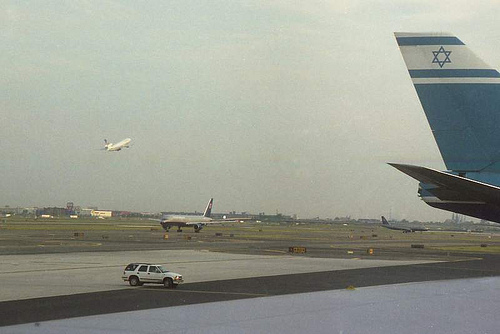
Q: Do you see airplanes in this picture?
A: Yes, there is an airplane.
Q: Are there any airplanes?
A: Yes, there is an airplane.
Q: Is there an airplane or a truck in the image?
A: Yes, there is an airplane.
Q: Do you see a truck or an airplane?
A: Yes, there is an airplane.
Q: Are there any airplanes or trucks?
A: Yes, there is an airplane.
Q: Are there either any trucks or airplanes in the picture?
A: Yes, there is an airplane.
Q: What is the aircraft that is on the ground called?
A: The aircraft is an airplane.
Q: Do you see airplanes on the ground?
A: Yes, there is an airplane on the ground.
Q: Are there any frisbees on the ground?
A: No, there is an airplane on the ground.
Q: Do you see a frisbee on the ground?
A: No, there is an airplane on the ground.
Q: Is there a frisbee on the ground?
A: No, there is an airplane on the ground.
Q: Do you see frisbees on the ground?
A: No, there is an airplane on the ground.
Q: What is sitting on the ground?
A: The airplane is sitting on the ground.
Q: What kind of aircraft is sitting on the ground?
A: The aircraft is an airplane.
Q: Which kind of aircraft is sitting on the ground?
A: The aircraft is an airplane.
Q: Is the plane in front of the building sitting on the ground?
A: Yes, the airplane is sitting on the ground.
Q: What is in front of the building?
A: The airplane is in front of the building.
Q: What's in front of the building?
A: The airplane is in front of the building.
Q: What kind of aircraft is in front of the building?
A: The aircraft is an airplane.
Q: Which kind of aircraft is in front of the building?
A: The aircraft is an airplane.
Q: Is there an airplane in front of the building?
A: Yes, there is an airplane in front of the building.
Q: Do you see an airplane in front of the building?
A: Yes, there is an airplane in front of the building.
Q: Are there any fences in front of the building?
A: No, there is an airplane in front of the building.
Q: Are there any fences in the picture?
A: No, there are no fences.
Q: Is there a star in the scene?
A: Yes, there is a star.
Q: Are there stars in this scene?
A: Yes, there is a star.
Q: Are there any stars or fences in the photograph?
A: Yes, there is a star.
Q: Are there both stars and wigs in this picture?
A: No, there is a star but no wigs.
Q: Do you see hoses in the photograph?
A: No, there are no hoses.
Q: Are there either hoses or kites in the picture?
A: No, there are no hoses or kites.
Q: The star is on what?
A: The star is on the plane.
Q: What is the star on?
A: The star is on the plane.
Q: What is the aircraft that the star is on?
A: The aircraft is an airplane.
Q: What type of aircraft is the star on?
A: The star is on the airplane.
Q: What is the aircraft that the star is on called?
A: The aircraft is an airplane.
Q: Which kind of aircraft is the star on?
A: The star is on the airplane.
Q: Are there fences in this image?
A: No, there are no fences.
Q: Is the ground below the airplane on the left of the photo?
A: Yes, the ground is below the plane.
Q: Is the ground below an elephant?
A: No, the ground is below the plane.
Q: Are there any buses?
A: No, there are no buses.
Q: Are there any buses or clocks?
A: No, there are no buses or clocks.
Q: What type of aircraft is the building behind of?
A: The building is behind the airplane.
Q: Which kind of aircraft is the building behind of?
A: The building is behind the airplane.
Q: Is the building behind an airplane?
A: Yes, the building is behind an airplane.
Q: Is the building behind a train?
A: No, the building is behind an airplane.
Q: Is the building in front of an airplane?
A: No, the building is behind an airplane.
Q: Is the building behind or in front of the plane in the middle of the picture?
A: The building is behind the plane.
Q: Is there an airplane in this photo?
A: Yes, there is an airplane.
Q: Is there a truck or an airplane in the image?
A: Yes, there is an airplane.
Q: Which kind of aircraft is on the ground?
A: The aircraft is an airplane.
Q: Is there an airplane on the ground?
A: Yes, there is an airplane on the ground.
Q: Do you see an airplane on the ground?
A: Yes, there is an airplane on the ground.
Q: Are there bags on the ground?
A: No, there is an airplane on the ground.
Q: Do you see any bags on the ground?
A: No, there is an airplane on the ground.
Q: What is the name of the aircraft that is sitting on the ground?
A: The aircraft is an airplane.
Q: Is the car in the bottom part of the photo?
A: Yes, the car is in the bottom of the image.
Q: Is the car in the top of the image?
A: No, the car is in the bottom of the image.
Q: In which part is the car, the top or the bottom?
A: The car is in the bottom of the image.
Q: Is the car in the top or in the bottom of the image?
A: The car is in the bottom of the image.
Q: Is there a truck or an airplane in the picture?
A: Yes, there is an airplane.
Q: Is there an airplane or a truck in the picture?
A: Yes, there is an airplane.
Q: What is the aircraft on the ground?
A: The aircraft is an airplane.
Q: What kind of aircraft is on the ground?
A: The aircraft is an airplane.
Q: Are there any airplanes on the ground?
A: Yes, there is an airplane on the ground.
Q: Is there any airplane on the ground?
A: Yes, there is an airplane on the ground.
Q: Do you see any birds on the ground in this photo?
A: No, there is an airplane on the ground.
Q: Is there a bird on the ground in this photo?
A: No, there is an airplane on the ground.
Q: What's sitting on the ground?
A: The plane is sitting on the ground.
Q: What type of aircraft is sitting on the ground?
A: The aircraft is an airplane.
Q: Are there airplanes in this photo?
A: Yes, there is an airplane.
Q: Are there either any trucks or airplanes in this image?
A: Yes, there is an airplane.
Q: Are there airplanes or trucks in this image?
A: Yes, there is an airplane.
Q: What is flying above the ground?
A: The airplane is flying above the ground.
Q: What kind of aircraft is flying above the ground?
A: The aircraft is an airplane.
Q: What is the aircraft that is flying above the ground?
A: The aircraft is an airplane.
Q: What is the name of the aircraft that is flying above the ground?
A: The aircraft is an airplane.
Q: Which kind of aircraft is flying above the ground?
A: The aircraft is an airplane.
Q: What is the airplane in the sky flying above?
A: The plane is flying above the ground.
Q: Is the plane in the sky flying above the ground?
A: Yes, the plane is flying above the ground.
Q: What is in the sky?
A: The airplane is in the sky.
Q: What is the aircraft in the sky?
A: The aircraft is an airplane.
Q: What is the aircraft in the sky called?
A: The aircraft is an airplane.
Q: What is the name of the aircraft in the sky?
A: The aircraft is an airplane.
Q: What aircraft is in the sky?
A: The aircraft is an airplane.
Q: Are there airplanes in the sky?
A: Yes, there is an airplane in the sky.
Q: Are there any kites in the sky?
A: No, there is an airplane in the sky.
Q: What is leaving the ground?
A: The airplane is leaving the ground.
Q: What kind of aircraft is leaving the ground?
A: The aircraft is an airplane.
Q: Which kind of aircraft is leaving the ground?
A: The aircraft is an airplane.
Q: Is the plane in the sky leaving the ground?
A: Yes, the plane is leaving the ground.